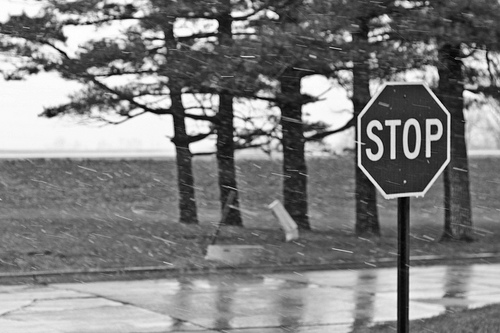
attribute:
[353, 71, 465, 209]
sign — black, white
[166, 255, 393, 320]
road — wet 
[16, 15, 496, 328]
photo — black, white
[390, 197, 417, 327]
pole — holding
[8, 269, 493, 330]
road — paved  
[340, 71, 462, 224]
sign — stop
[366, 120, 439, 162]
writing — white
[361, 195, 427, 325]
pole — metal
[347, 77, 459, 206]
sign — stop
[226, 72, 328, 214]
trees — group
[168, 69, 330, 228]
trees — behind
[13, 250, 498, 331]
street — wet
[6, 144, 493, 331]
ground — wet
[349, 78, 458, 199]
border — white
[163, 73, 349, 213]
trunk — tree